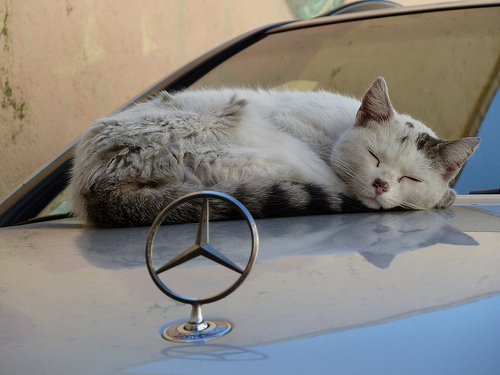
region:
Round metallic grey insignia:
[139, 185, 263, 350]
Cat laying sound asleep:
[62, 69, 484, 224]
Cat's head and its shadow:
[326, 73, 486, 276]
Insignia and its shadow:
[141, 183, 273, 368]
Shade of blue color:
[118, 293, 499, 373]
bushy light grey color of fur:
[63, 83, 335, 183]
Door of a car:
[1, 0, 498, 231]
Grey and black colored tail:
[79, 177, 367, 227]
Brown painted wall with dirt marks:
[1, 0, 305, 224]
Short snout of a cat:
[357, 171, 399, 220]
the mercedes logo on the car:
[145, 192, 258, 302]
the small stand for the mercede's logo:
[185, 304, 208, 330]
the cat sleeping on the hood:
[70, 75, 479, 210]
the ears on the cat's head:
[352, 76, 482, 183]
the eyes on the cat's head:
[363, 144, 424, 184]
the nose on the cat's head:
[372, 177, 389, 196]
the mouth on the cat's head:
[357, 190, 385, 211]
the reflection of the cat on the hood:
[72, 208, 477, 270]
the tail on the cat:
[90, 179, 364, 226]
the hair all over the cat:
[67, 77, 482, 229]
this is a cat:
[86, 94, 422, 191]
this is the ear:
[352, 67, 398, 116]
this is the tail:
[120, 187, 317, 220]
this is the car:
[255, 238, 453, 373]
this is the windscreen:
[284, 28, 366, 61]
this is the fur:
[329, 156, 351, 182]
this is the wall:
[29, 9, 108, 83]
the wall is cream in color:
[31, 22, 106, 79]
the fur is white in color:
[330, 147, 347, 181]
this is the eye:
[363, 143, 383, 166]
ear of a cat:
[358, 71, 407, 128]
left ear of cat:
[436, 123, 488, 179]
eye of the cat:
[351, 140, 396, 177]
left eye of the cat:
[395, 157, 434, 194]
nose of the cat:
[364, 171, 395, 202]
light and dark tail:
[249, 175, 336, 217]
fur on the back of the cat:
[107, 100, 215, 170]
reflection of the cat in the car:
[355, 218, 434, 268]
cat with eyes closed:
[315, 86, 475, 218]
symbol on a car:
[92, 175, 297, 339]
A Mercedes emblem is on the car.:
[4, 3, 497, 373]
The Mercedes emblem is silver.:
[116, 175, 277, 355]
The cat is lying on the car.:
[2, 0, 498, 371]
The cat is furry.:
[43, 48, 490, 263]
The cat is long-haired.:
[56, 49, 491, 238]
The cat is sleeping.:
[57, 64, 471, 251]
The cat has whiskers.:
[307, 73, 486, 231]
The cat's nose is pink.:
[294, 56, 480, 233]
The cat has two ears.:
[297, 53, 487, 229]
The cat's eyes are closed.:
[301, 65, 488, 235]